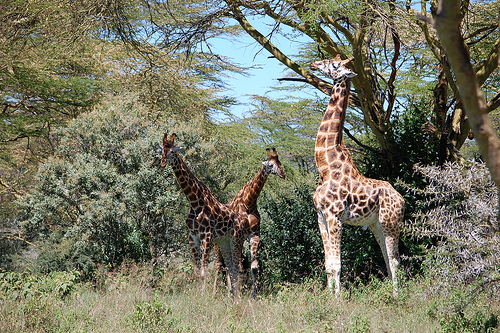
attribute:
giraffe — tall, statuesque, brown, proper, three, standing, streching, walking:
[266, 45, 428, 309]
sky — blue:
[251, 74, 269, 87]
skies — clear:
[253, 58, 276, 84]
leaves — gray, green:
[276, 35, 319, 80]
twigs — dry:
[128, 248, 180, 303]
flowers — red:
[419, 169, 480, 239]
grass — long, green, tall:
[125, 273, 195, 329]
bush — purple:
[411, 170, 487, 267]